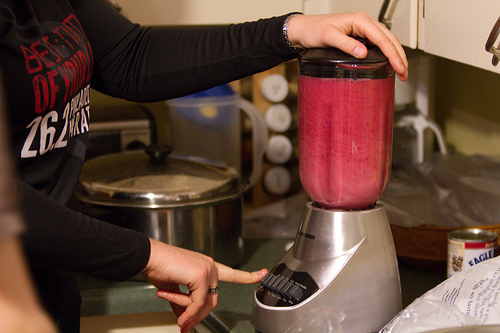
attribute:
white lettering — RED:
[17, 112, 42, 165]